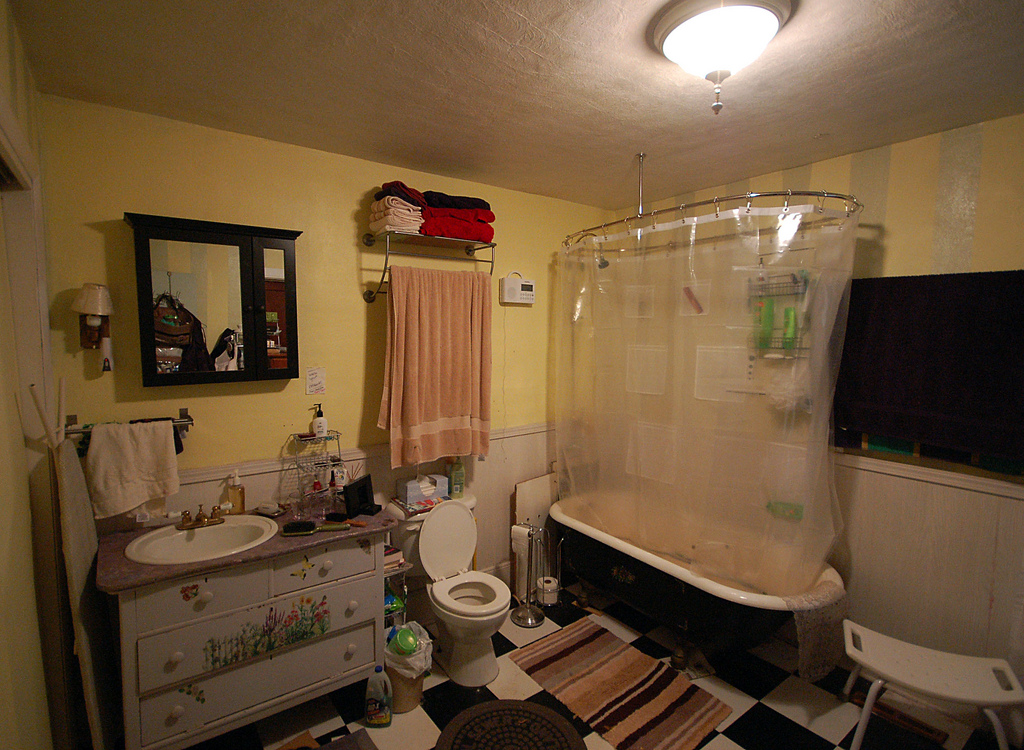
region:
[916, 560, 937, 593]
a tile in a wall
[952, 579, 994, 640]
a tile in a wall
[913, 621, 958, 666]
a tile in a wall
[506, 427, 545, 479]
a tile in a wall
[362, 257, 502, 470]
the towel is color pink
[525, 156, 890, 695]
a curtain on a bathtub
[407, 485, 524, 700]
the toilet is white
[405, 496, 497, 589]
the lid of a toilet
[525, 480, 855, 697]
the bathtub is white and brown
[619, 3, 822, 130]
a light on the ceiling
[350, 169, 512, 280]
towels on a shelf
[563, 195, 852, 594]
the curtain is clear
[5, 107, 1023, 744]
the walls are yellow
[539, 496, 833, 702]
the tub is white and black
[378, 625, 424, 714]
the garbage is full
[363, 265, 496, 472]
the towel is pink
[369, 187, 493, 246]
the towels are stacked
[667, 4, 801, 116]
the light is on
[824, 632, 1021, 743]
the bench is white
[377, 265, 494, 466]
A pink towel hanging on a rack.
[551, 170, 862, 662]
A tub with a shower curtain.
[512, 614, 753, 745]
A brown stripped rug on a floor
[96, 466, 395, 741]
A wash basen in a stand.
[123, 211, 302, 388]
A black mirror on a wall.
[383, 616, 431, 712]
A trash can full of trash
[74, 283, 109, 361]
A lamp on the wall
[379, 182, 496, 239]
folded towels on a rack.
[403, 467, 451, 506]
A tissue box on a toliet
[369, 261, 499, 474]
A towel hanging from the towel rack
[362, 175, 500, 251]
Folded towels on the shelf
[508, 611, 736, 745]
Striped rug in front of the toilet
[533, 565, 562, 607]
Roll of toilet paper on the floor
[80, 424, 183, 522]
Towel hanging above the sink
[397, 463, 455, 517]
Tissues on top of the toilet tank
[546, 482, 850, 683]
Old-fashioned claw-foot tub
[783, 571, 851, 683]
Plastic bath mat hanging from tub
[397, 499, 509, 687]
white toilet in messy bathroom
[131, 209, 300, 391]
brown square mirror hanging in yellow wall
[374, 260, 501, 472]
pink bath towel hanging in yellow wall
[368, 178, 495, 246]
bath towels bended on top of shelf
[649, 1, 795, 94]
ceiling light hanging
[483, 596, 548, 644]
white tile on floor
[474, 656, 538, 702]
white tile on floor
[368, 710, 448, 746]
white tile on floor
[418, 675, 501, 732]
black tile on floor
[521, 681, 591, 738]
black tile on floor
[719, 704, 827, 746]
black tile on floor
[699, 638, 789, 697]
black tile on floor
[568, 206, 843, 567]
There is a clear shower curtain hanging up.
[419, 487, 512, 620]
The toilet seat was left hanging up.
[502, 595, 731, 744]
There is a striped rug on the floor.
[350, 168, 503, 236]
Towels are folded above on the shelf above the toilet.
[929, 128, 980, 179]
A tile in a wall.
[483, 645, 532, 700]
A tile in a floor.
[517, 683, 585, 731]
A tile in a floor.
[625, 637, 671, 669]
A tile in a floor.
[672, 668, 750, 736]
A tile in a floor.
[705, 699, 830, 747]
A tile in a floor.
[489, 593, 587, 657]
A tile in a floor.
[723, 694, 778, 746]
A tile in a floor.